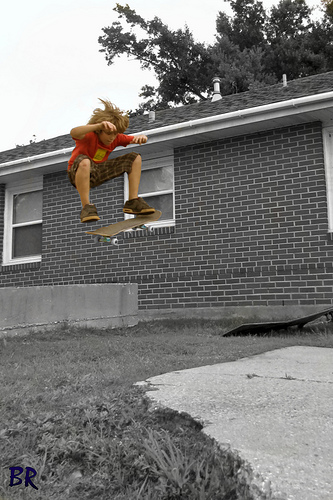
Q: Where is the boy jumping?
A: Air.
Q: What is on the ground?
A: Grass.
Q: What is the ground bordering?
A: Cement block.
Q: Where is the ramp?
A: Road.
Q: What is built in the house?
A: Window.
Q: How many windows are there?
A: Two.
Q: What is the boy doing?
A: Skateboarding.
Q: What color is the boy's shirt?
A: Red.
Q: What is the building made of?
A: Bricks.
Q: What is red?
A: Boy's shirt.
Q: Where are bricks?
A: On house.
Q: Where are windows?
A: On the house.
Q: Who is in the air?
A: Skateboarder.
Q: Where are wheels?
A: On skateboard.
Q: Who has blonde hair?
A: The skateboarder.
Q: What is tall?
A: A tree.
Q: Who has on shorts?
A: The boy.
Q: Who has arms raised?
A: Boy.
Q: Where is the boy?
A: In the air.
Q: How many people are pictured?
A: One.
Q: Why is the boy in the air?
A: Doing a trick.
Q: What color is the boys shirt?
A: Red.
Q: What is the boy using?
A: A skateboard.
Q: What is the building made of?
A: Brick.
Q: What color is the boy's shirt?
A: Orange.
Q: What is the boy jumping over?
A: Grass.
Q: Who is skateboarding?
A: A boy.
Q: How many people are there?
A: 1.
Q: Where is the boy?
A: In mid-air.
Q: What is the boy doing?
A: A trick.